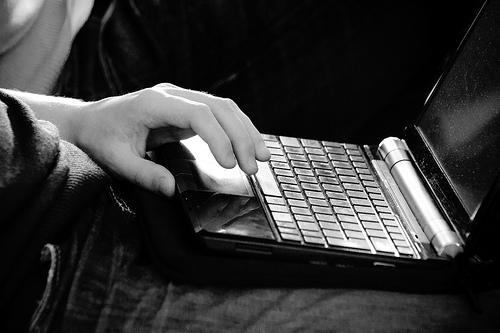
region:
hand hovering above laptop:
[40, 56, 287, 221]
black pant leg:
[42, 205, 497, 329]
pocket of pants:
[0, 215, 103, 328]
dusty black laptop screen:
[413, 1, 498, 240]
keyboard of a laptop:
[243, 114, 426, 261]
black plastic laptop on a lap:
[133, 0, 498, 285]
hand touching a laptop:
[70, 85, 301, 230]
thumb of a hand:
[147, 170, 175, 196]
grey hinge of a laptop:
[368, 132, 463, 255]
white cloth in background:
[0, 0, 81, 72]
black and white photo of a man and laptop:
[10, 22, 491, 317]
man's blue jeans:
[20, 235, 171, 330]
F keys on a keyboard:
[350, 141, 367, 181]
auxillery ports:
[297, 246, 362, 271]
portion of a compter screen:
[411, 111, 493, 161]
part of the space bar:
[255, 171, 277, 188]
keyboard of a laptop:
[270, 132, 387, 239]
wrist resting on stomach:
[40, 92, 120, 177]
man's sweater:
[2, 142, 82, 237]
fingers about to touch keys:
[91, 70, 296, 215]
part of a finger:
[210, 133, 235, 170]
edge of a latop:
[286, 258, 318, 292]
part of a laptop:
[270, 236, 303, 278]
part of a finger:
[138, 155, 204, 220]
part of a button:
[291, 210, 328, 257]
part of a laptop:
[329, 185, 380, 233]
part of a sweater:
[55, 142, 92, 189]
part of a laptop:
[305, 199, 358, 275]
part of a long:
[109, 200, 151, 233]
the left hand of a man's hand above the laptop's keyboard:
[0, 80, 272, 196]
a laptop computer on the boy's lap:
[90, 1, 498, 331]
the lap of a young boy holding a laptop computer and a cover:
[0, 0, 495, 330]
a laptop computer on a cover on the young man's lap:
[145, 0, 495, 275]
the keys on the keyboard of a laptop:
[266, 130, 411, 256]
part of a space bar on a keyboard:
[255, 160, 277, 195]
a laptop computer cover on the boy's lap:
[125, 200, 470, 287]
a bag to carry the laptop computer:
[70, 0, 429, 80]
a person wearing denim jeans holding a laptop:
[1, 2, 498, 330]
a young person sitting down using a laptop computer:
[2, 1, 497, 331]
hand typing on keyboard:
[97, 69, 433, 258]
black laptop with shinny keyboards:
[177, 0, 488, 307]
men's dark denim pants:
[25, 197, 282, 332]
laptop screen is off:
[412, 2, 492, 209]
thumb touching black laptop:
[102, 130, 196, 215]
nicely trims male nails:
[200, 122, 282, 193]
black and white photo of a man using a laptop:
[4, 3, 498, 306]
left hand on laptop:
[44, 66, 474, 276]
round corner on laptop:
[368, 127, 490, 289]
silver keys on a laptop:
[251, 124, 420, 268]